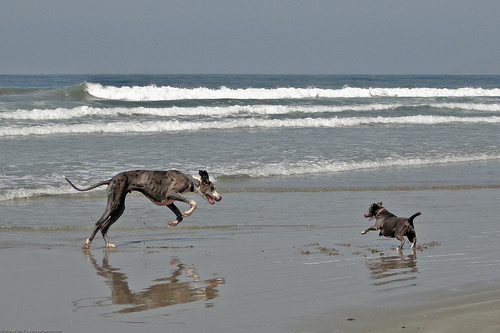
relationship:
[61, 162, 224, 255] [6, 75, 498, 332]
dog at beach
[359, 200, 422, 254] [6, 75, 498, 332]
dog at beach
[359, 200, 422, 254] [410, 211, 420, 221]
dog has tail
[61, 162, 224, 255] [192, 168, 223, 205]
dog has head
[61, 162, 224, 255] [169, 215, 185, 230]
dog has front foot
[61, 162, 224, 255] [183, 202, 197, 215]
dog has front foot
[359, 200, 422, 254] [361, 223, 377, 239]
dog has front foot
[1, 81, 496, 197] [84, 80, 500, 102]
ocean has wave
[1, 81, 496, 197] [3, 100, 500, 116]
ocean has wave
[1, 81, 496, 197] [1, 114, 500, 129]
ocean has wave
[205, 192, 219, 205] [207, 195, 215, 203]
mouth has inside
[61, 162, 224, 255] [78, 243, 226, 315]
dog has shadow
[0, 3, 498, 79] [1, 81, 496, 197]
sky above ocean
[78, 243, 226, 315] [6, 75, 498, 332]
shadow across beach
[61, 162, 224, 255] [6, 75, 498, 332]
dog on top of beach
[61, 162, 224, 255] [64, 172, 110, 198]
dog has tail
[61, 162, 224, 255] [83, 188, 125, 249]
dog has leg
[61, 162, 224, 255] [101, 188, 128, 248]
dog has leg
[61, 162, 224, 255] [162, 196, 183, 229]
dog has leg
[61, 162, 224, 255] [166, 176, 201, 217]
dog has leg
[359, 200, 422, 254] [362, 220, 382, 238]
dog has leg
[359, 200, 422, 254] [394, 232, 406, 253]
dog has leg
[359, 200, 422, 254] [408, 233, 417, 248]
dog has leg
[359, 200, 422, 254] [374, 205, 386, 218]
dog has collar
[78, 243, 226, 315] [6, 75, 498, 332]
shadow at beach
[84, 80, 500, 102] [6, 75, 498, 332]
wave breaking against beach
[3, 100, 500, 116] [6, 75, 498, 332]
wave breaking against beach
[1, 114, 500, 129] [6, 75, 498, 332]
wave breaking against beach